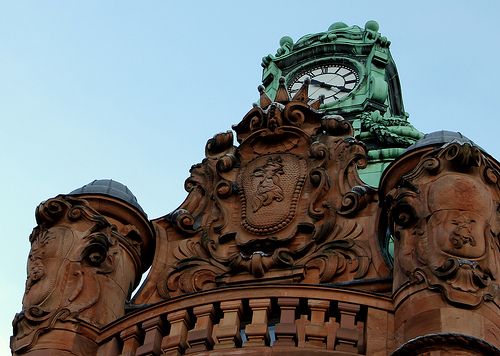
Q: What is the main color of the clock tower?
A: Green.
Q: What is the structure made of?
A: Stone.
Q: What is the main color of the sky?
A: Blue.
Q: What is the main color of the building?
A: Brown.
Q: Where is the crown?
A: Below the clock.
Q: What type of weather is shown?
A: Clear.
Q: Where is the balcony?
A: Bottom of the image.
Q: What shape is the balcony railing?
A: Round.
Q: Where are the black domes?
A: Top of the corners posts.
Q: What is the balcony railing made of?
A: Wood.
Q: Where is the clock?
A: Top of building.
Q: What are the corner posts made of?
A: Wood.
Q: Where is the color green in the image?
A: Clock housing.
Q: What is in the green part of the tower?
A: Clock.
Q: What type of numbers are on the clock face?
A: Roman.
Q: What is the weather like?
A: Sunny.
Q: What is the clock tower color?
A: Green.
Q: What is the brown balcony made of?
A: Stone.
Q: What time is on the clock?
A: 10:20.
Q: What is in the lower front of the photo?
A: Balcony.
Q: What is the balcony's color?
A: Brown.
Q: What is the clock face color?
A: White.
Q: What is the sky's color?
A: Blue.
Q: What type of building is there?
A: A large green and brown one.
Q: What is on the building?
A: A clock.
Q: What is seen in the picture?
A: Ancient statue.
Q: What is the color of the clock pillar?
A: Green.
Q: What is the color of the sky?
A: Blue.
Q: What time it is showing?
A: 10:20.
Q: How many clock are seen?
A: 1.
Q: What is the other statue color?
A: Red.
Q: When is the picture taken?
A: Daytime.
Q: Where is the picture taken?
A: Clocktower.